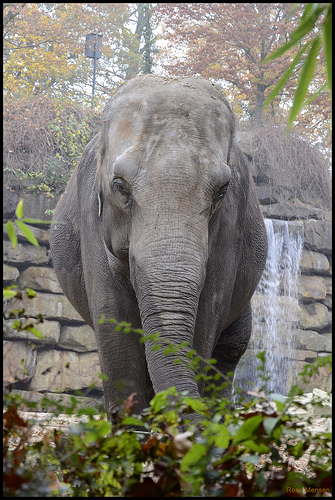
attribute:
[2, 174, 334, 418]
wall — stones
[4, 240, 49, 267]
stone — white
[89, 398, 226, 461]
leaves — brown , green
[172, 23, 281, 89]
trees — orange